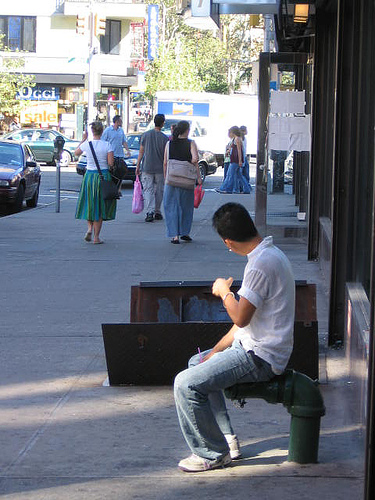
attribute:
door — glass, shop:
[248, 47, 332, 243]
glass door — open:
[257, 45, 307, 241]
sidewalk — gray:
[1, 183, 353, 497]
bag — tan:
[162, 155, 202, 190]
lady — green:
[73, 124, 118, 254]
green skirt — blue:
[67, 165, 122, 246]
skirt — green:
[77, 173, 119, 245]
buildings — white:
[1, 2, 279, 150]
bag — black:
[87, 138, 124, 200]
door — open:
[129, 279, 318, 324]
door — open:
[98, 321, 321, 388]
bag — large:
[157, 136, 207, 191]